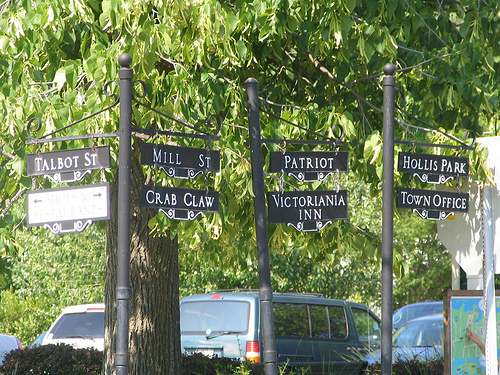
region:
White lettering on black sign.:
[268, 180, 397, 246]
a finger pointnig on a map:
[449, 294, 484, 373]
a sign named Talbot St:
[24, 147, 116, 174]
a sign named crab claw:
[140, 184, 221, 220]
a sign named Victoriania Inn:
[266, 187, 351, 232]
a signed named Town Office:
[393, 184, 473, 224]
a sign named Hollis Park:
[397, 149, 470, 186]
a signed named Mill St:
[141, 142, 219, 182]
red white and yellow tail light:
[243, 339, 263, 364]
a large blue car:
[180, 289, 387, 367]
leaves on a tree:
[149, 34, 232, 101]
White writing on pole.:
[274, 122, 384, 194]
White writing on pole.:
[261, 177, 360, 221]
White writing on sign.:
[144, 131, 251, 201]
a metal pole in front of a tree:
[106, 56, 151, 358]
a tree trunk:
[128, 229, 179, 366]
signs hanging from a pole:
[266, 133, 356, 226]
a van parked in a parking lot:
[188, 292, 393, 351]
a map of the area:
[451, 301, 493, 373]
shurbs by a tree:
[11, 336, 101, 372]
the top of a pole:
[116, 53, 139, 79]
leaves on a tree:
[191, 6, 462, 56]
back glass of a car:
[51, 309, 107, 343]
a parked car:
[372, 309, 452, 360]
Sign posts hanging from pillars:
[23, 140, 470, 234]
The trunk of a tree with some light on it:
[131, 239, 178, 374]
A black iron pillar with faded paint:
[114, 63, 131, 373]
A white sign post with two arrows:
[25, 182, 110, 233]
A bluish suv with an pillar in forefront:
[181, 290, 383, 373]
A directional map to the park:
[444, 289, 499, 374]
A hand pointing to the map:
[461, 325, 486, 361]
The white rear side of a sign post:
[436, 135, 498, 287]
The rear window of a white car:
[47, 305, 105, 345]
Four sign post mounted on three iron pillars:
[117, 134, 470, 233]